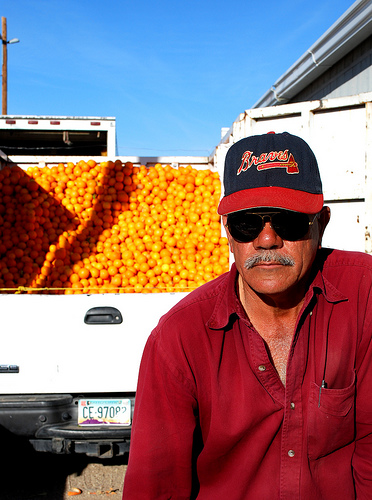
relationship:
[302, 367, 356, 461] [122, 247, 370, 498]
pocket of shirt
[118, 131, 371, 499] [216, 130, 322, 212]
man has baseball hat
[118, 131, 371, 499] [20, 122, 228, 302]
man selling fruit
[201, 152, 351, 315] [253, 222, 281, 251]
man has nose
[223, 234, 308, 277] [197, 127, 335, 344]
mustache on a man's face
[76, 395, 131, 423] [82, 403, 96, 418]
license plate starts with ce